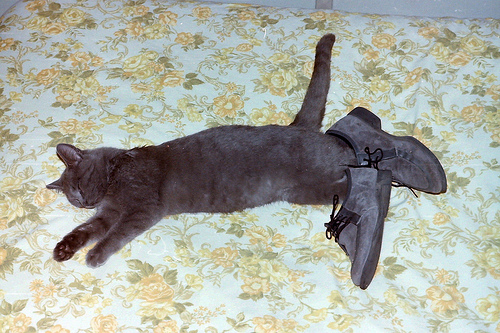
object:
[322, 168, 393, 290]
shoe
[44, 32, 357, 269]
cat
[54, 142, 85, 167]
ear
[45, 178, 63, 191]
ear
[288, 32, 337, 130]
tail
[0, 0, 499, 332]
comforter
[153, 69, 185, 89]
flower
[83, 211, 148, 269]
legs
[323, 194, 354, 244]
laces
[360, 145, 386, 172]
shoe laces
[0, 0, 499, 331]
table cloth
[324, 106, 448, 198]
shoe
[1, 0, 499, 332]
bed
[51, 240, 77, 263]
front paw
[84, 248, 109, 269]
front paw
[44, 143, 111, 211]
head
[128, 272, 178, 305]
flowers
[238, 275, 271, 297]
flowers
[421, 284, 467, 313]
flowers